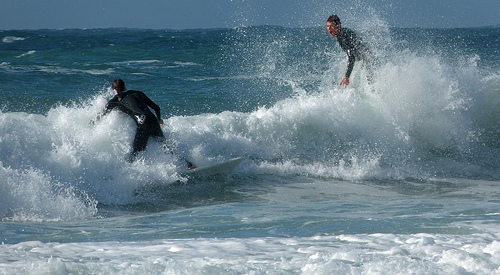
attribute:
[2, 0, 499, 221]
spray — white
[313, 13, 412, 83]
wetsuit — black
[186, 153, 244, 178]
board — white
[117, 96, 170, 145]
wetsuit — black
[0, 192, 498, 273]
water — white and foamy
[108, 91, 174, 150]
wetsuit — black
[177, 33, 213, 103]
ocean — green, blue, beautiful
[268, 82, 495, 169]
wave — very tall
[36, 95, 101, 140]
water — splash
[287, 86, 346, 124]
water — splash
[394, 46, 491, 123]
water — splash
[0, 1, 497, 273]
water — very rough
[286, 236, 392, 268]
water — white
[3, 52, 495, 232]
wave — white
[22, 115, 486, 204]
wave — white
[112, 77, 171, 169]
wetsuit — black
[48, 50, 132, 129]
skyline — blue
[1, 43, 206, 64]
water — still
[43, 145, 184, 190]
droplets — white